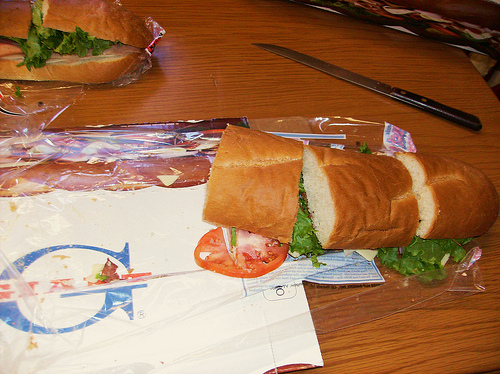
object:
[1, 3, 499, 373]
table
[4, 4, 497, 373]
photo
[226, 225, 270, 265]
slice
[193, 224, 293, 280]
tomato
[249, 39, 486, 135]
knife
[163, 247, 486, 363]
wrapper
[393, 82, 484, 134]
handle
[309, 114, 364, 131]
plastic bag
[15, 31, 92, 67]
vegetables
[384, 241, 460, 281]
lettuce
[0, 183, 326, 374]
paper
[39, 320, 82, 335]
box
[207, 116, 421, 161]
plastic wrap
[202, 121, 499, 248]
sub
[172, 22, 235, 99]
table top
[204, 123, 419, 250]
slices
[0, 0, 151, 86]
bread loaf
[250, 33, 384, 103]
blade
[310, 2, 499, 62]
bread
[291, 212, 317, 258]
leafy stuffing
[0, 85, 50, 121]
plastic cover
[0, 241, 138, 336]
g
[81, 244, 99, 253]
blue color